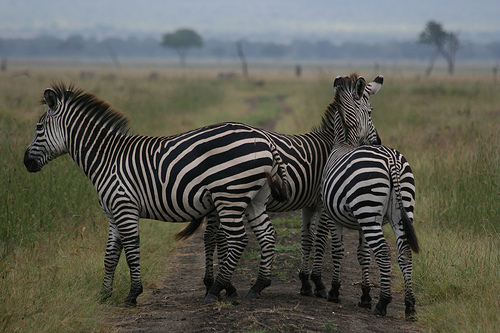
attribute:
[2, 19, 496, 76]
forested area — large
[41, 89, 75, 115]
ear — black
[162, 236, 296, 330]
road — grey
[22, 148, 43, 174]
nose — black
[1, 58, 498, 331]
grass — green, brown, yellow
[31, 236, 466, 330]
grass — green, brown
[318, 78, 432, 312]
zebra — white, black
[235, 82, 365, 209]
zebra — white, black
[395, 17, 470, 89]
tree — tall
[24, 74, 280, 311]
zebra — black, white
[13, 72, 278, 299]
zebra — walking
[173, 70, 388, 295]
zebra — walking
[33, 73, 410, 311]
zebras — standing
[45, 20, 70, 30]
clouds — white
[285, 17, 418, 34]
clouds — white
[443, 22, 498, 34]
clouds — white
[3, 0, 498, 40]
sky — blue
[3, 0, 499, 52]
sky — blue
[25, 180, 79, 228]
grass — green, brown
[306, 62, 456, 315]
zebras — leaning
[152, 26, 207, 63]
tree — distant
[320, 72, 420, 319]
zebra — walking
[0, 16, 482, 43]
clouds — white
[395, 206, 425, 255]
tail — black